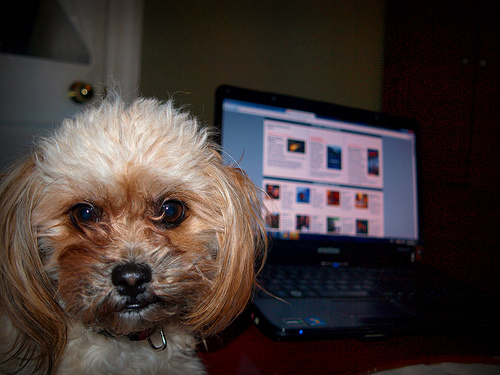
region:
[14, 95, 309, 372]
the face of a dog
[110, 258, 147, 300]
black nose on dog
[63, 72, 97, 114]
a gold door handle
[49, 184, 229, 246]
brown eyes of dog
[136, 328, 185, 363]
a metal loop on dog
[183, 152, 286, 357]
long brown hair on ears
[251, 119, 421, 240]
pictures on the laptop screen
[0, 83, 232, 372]
a white and brown dog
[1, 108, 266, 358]
dog with long hair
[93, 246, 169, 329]
part of dog's face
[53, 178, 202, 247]
hairy dog's brown eyes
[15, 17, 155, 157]
part of a door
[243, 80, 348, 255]
part of a computer screen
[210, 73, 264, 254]
part of a computer screen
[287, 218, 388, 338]
part of a computer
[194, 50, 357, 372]
part of a lap top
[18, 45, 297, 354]
hairy dog and part of a computer screen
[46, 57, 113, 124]
part of a door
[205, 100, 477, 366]
black laptop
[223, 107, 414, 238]
webpage open on screen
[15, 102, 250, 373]
dog staring at camera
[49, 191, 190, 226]
dog has brown eyes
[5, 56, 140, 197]
white door behind dog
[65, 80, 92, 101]
gold door knob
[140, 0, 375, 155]
beige walls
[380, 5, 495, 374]
burgundy wall on the side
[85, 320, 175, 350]
dog collar on the dog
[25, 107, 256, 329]
head of a dog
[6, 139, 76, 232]
ear of a dog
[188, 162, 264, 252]
ear of a dog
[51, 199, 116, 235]
eye of a dog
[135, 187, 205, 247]
eye of a dog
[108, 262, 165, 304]
nose of a dog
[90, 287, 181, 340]
mouth of a dog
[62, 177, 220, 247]
eyes of a dog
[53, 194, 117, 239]
an eye of a dog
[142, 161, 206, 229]
an eye of a dog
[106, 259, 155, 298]
Black nose on a dog's face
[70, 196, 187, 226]
Two eyes on a light brown dog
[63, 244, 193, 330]
Snout of a small, brown dog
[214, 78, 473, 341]
A black laptop on a desk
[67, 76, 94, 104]
The knob on a white door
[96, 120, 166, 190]
Fur on a small dog's head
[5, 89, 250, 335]
Head of a small, brown dog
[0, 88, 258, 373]
Small dog staring at the camera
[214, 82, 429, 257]
The monitor of an open laptop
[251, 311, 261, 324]
Audio ports on the side of a laptop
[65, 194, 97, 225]
the dogs eye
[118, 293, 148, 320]
the dogs lips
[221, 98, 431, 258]
a monitor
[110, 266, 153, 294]
the dogs nose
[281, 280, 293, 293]
A key on a keyboard.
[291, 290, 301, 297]
A key on a keyboard.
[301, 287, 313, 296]
A key on a keyboard.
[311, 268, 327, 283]
A key on a keyboard.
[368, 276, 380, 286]
A key on a keyboard.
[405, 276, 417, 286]
A key on a keyboard.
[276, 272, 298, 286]
A key on a keyboard.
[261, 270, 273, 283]
A key on a keyboard.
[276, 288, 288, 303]
A key on a keyboard.